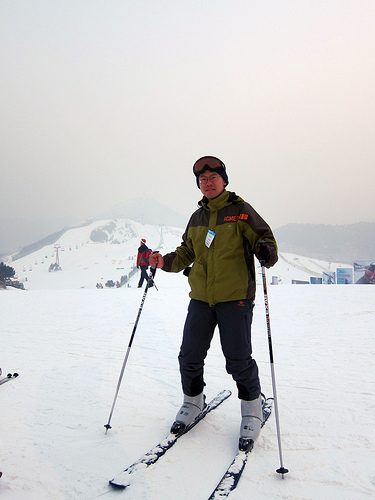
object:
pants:
[179, 297, 261, 402]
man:
[162, 156, 278, 441]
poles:
[104, 251, 160, 436]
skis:
[205, 398, 277, 500]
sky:
[1, 1, 372, 263]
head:
[198, 156, 228, 198]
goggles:
[193, 157, 223, 173]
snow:
[120, 436, 244, 494]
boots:
[239, 395, 264, 441]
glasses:
[197, 174, 222, 183]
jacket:
[162, 191, 277, 308]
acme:
[222, 215, 241, 222]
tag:
[205, 229, 216, 249]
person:
[137, 238, 156, 287]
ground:
[4, 290, 374, 499]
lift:
[53, 243, 61, 265]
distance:
[13, 203, 362, 285]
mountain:
[8, 219, 355, 291]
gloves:
[255, 241, 277, 268]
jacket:
[137, 245, 151, 268]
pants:
[138, 266, 154, 288]